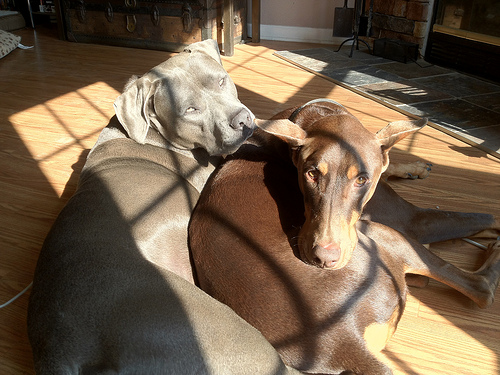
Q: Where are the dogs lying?
A: On the floor.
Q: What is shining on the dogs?
A: Sun.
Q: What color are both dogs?
A: Brown.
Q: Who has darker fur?
A: One of the dogs.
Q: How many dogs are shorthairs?
A: Both dogs.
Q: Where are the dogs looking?
A: At the camera.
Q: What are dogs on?
A: Hardwood floor.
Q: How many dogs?
A: Two.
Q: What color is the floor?
A: Brown.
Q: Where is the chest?
A: Under the table.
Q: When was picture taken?
A: During Daylight Hours.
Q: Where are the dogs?
A: Living room.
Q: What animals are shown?
A: Dogs.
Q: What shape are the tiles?
A: Square.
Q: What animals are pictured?
A: Dogs.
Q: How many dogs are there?
A: Two.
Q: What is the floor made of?
A: Wood.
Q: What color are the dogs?
A: Grey and brown.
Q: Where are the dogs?
A: On the floor.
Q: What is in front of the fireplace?
A: Stone tiles.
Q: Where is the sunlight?
A: Over the dog's bodies.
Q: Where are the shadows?
A: On the dogs.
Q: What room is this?
A: A living room.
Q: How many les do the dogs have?
A: Four.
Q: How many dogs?
A: Two.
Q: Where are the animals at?
A: Inside a house.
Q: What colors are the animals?
A: Brown and gray.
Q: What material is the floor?
A: Hardwood.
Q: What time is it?
A: During the day time.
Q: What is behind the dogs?
A: A wooden chest.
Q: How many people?
A: None.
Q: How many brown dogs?
A: One.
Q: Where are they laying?
A: On the floor.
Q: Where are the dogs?
A: In a house.